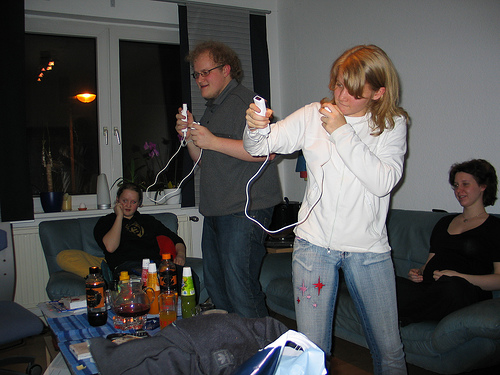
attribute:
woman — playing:
[241, 42, 410, 373]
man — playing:
[174, 41, 282, 318]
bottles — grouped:
[85, 252, 197, 327]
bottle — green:
[179, 267, 197, 319]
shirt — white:
[242, 101, 408, 253]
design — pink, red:
[296, 276, 326, 308]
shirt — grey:
[199, 76, 284, 216]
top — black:
[422, 214, 499, 281]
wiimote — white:
[252, 95, 272, 139]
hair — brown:
[449, 158, 498, 206]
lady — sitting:
[397, 158, 499, 326]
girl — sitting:
[93, 182, 201, 307]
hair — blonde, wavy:
[185, 39, 244, 83]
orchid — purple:
[142, 141, 160, 160]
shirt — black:
[93, 209, 186, 272]